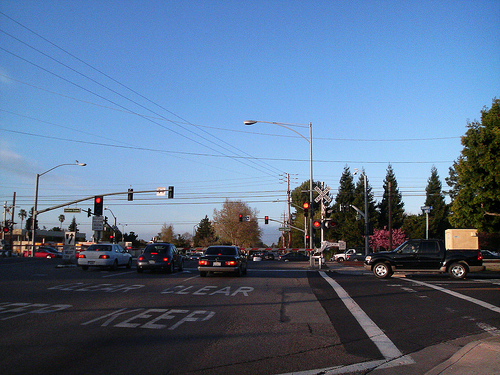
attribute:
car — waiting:
[185, 243, 248, 293]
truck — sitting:
[355, 242, 487, 292]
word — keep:
[86, 289, 216, 349]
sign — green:
[45, 205, 99, 209]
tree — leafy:
[80, 204, 119, 239]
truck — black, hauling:
[361, 226, 472, 286]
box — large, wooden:
[436, 221, 487, 252]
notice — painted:
[119, 273, 248, 373]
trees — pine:
[317, 136, 445, 229]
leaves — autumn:
[203, 180, 260, 247]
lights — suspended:
[216, 188, 305, 226]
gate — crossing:
[295, 242, 338, 262]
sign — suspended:
[39, 182, 102, 221]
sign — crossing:
[298, 164, 366, 223]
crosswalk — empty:
[316, 257, 476, 347]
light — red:
[77, 190, 142, 220]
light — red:
[297, 208, 338, 254]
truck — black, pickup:
[355, 232, 496, 278]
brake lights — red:
[194, 253, 259, 277]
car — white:
[53, 229, 164, 306]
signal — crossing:
[274, 196, 360, 276]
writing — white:
[100, 268, 300, 368]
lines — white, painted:
[325, 257, 473, 368]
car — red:
[26, 231, 88, 277]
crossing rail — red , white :
[224, 240, 333, 264]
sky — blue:
[236, 14, 479, 112]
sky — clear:
[191, 19, 394, 112]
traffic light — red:
[88, 188, 103, 223]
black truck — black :
[370, 238, 484, 284]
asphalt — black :
[224, 305, 294, 356]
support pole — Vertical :
[305, 118, 317, 281]